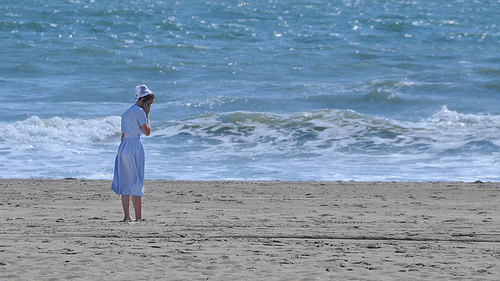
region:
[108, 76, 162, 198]
woman wearing dress on beach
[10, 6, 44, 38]
blue and white ocean waves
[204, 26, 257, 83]
blue and white ocean waves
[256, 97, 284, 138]
blue and white ocean waves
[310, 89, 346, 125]
blue and white ocean waves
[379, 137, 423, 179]
blue and white ocean waves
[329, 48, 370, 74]
blue and white ocean waves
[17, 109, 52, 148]
blue and white ocean waves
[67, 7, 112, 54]
blue and white ocean waves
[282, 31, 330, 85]
blue and white ocean waves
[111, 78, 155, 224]
A woman on the beach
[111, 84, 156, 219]
Woman is wearing a dress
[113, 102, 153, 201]
The dress is white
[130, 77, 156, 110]
Woman is wearing a hat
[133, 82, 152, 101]
The hat is white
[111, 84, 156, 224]
The woman is talking on the phone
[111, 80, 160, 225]
The woman is standing on the sand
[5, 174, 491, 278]
The sand is tan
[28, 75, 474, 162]
Waves crashing onto shore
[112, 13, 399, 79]
The water is blue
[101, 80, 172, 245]
woman standing in sand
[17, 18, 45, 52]
white and blue ocean waves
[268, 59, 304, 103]
white and blue ocean waves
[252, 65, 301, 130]
white and blue ocean waves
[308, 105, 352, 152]
white and blue ocean waves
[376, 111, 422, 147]
white and blue ocean waves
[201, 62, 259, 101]
white and blue ocean waves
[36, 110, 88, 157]
white and blue ocean waves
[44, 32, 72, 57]
white and blue ocean waves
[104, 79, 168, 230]
Person in a white dress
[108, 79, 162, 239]
White dress on the beach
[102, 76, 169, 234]
Woman in a white dress on the beach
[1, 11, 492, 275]
Woman on the beach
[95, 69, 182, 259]
Woman in white cap on the beach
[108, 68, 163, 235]
Woman touching face on the beach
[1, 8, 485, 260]
Woman on a sandy beach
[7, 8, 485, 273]
Woman on the beach touching face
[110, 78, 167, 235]
Woman in flowing dress on the beach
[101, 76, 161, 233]
Woman in white flowing dress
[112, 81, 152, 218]
a woman standing on the beach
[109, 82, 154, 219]
a woman talking on the phone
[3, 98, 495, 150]
a wave washing on shore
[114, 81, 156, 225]
a woman with her feet in the sand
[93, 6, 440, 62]
ripples in the water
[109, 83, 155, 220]
a woman in a white dress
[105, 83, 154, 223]
a white dress on a woman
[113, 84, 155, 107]
a hat on the woman's head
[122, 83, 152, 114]
a woman holding a phone with her right hand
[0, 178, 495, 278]
sand in front of the water